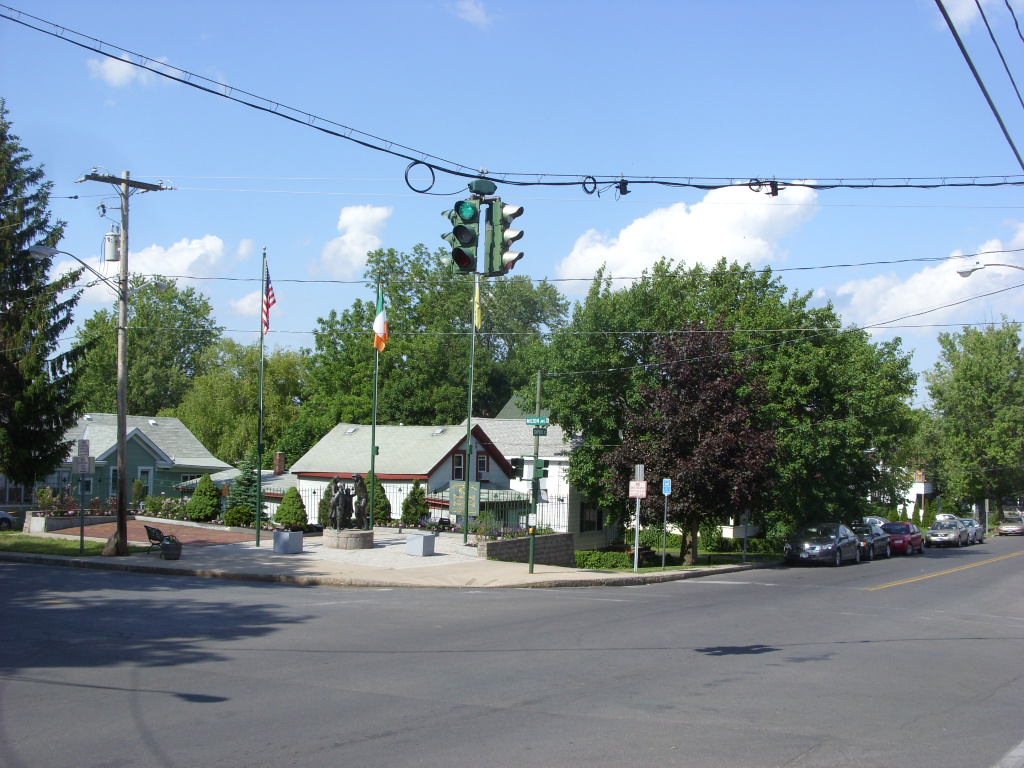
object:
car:
[999, 518, 1024, 538]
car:
[959, 518, 986, 544]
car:
[881, 522, 927, 556]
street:
[0, 535, 1024, 767]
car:
[848, 523, 891, 560]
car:
[785, 523, 862, 567]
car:
[925, 520, 971, 548]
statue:
[328, 473, 369, 532]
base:
[323, 529, 373, 550]